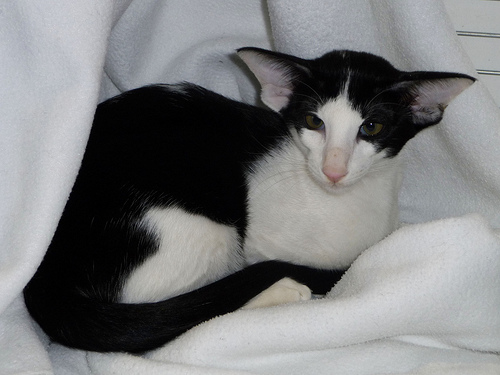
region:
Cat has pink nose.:
[320, 158, 342, 192]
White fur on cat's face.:
[323, 100, 383, 169]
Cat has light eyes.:
[304, 101, 419, 141]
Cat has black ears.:
[261, 34, 493, 82]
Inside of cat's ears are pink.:
[251, 65, 321, 115]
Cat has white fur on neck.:
[295, 177, 358, 257]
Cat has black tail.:
[152, 271, 277, 350]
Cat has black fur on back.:
[111, 112, 201, 159]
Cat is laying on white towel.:
[243, 260, 400, 367]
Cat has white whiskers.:
[263, 142, 305, 202]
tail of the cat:
[46, 255, 343, 362]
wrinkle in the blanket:
[340, 324, 491, 362]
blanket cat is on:
[352, 238, 496, 331]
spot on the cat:
[99, 181, 213, 301]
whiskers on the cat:
[241, 153, 313, 193]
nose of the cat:
[302, 152, 362, 192]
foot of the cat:
[271, 273, 316, 323]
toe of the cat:
[286, 286, 306, 303]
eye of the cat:
[341, 112, 388, 160]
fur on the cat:
[118, 201, 203, 303]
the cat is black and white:
[109, 44, 384, 235]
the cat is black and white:
[48, 16, 434, 362]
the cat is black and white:
[145, 124, 356, 284]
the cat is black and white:
[224, 159, 373, 266]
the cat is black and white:
[189, 128, 310, 205]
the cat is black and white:
[281, 92, 430, 324]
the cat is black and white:
[201, 0, 403, 279]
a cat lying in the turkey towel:
[26, 14, 471, 359]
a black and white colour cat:
[54, 71, 406, 283]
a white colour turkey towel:
[442, 111, 491, 348]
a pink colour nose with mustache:
[286, 72, 406, 199]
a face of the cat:
[235, 20, 466, 205]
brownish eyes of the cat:
[295, 108, 415, 142]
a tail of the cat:
[9, 250, 362, 360]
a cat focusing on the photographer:
[44, 27, 459, 337]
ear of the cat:
[228, 30, 480, 115]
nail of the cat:
[294, 281, 320, 306]